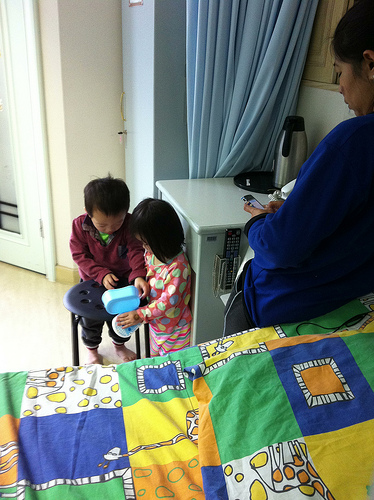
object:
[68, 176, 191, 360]
kids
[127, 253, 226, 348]
shirt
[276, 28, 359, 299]
woman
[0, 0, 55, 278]
door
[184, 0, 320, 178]
curtain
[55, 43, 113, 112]
wall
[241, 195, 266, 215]
phone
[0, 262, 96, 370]
floor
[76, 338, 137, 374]
foot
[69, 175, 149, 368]
boy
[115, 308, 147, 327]
hand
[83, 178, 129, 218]
hair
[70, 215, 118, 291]
arm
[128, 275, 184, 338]
head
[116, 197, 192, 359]
girl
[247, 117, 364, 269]
arm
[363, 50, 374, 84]
ear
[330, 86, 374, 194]
head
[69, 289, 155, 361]
jacket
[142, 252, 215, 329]
polka dots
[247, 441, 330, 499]
giraffe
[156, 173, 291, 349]
cabinet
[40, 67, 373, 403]
kitchen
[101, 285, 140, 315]
bowl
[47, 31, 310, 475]
room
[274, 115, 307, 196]
pitcher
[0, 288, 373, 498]
bedspread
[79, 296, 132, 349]
pants